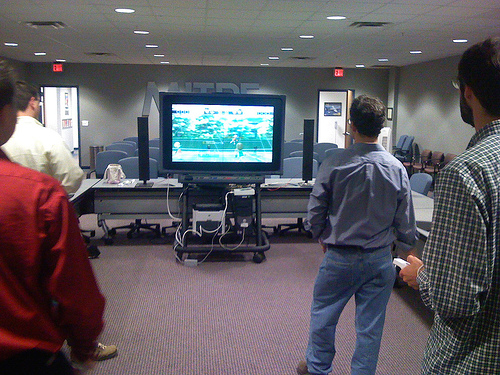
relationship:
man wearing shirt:
[299, 96, 417, 373] [320, 142, 414, 257]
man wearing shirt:
[12, 79, 101, 191] [23, 116, 80, 178]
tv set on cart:
[131, 71, 313, 204] [138, 157, 295, 301]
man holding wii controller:
[399, 39, 498, 375] [387, 252, 409, 270]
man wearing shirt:
[7, 79, 119, 360] [1, 112, 84, 198]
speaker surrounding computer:
[130, 112, 157, 186] [154, 87, 289, 238]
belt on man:
[327, 234, 397, 252] [276, 92, 442, 373]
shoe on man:
[80, 342, 120, 359] [9, 73, 129, 360]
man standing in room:
[295, 96, 417, 373] [1, 8, 499, 373]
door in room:
[36, 82, 79, 159] [1, 8, 499, 373]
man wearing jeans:
[299, 96, 417, 373] [307, 245, 398, 370]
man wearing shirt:
[399, 39, 498, 375] [412, 117, 498, 374]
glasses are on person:
[447, 72, 464, 93] [421, 43, 498, 368]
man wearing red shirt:
[2, 63, 106, 375] [2, 160, 102, 362]